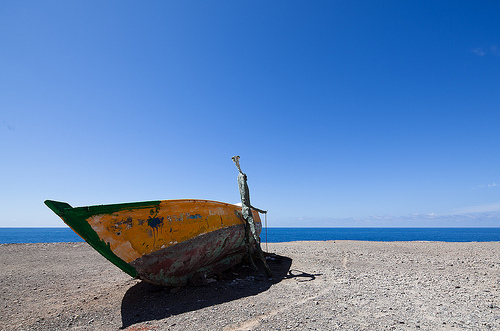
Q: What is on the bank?
A: Boat.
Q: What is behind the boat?
A: Sea.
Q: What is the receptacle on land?
A: Boat.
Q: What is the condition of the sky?
A: Clear.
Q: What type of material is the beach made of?
A: Rocks.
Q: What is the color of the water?
A: Blue.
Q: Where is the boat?
A: On the shore.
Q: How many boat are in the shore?
A: One.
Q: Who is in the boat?
A: No one.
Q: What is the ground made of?
A: Sands.